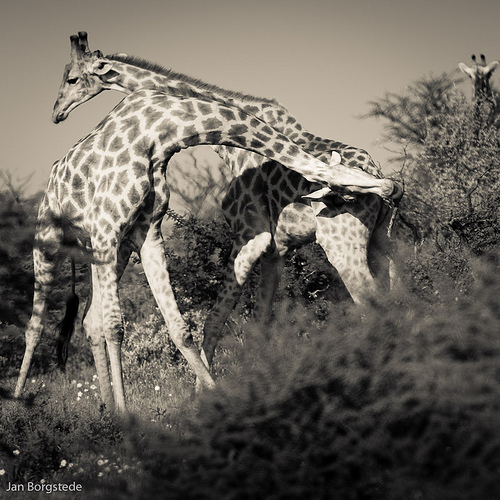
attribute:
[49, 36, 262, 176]
giraffe — fighting, bending, scratching, three, spotted, hiding, eating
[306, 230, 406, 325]
leg — long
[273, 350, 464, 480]
bush — blurry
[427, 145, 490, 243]
tree — gnarled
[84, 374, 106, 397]
flowers — small, white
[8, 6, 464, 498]
photo — black, white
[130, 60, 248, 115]
neck — bent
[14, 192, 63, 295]
vegetation — dry